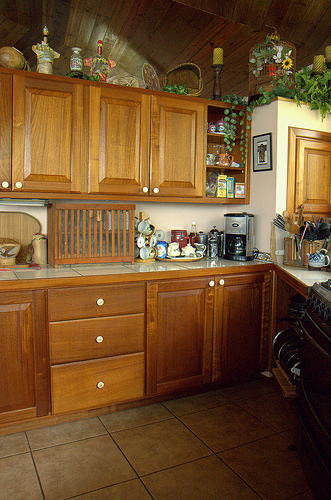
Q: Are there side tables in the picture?
A: No, there are no side tables.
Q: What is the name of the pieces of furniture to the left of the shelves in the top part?
A: The pieces of furniture are cabinets.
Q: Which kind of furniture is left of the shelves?
A: The pieces of furniture are cabinets.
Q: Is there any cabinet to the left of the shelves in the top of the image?
A: Yes, there are cabinets to the left of the shelves.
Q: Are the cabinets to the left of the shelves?
A: Yes, the cabinets are to the left of the shelves.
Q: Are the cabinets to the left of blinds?
A: No, the cabinets are to the left of the shelves.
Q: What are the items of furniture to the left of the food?
A: The pieces of furniture are cabinets.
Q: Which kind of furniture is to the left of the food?
A: The pieces of furniture are cabinets.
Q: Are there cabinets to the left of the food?
A: Yes, there are cabinets to the left of the food.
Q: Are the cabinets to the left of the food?
A: Yes, the cabinets are to the left of the food.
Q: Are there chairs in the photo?
A: No, there are no chairs.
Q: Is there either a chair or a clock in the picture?
A: No, there are no chairs or clocks.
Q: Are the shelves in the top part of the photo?
A: Yes, the shelves are in the top of the image.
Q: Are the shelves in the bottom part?
A: No, the shelves are in the top of the image.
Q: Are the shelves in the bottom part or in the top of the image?
A: The shelves are in the top of the image.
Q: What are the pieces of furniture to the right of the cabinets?
A: The pieces of furniture are shelves.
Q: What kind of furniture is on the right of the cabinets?
A: The pieces of furniture are shelves.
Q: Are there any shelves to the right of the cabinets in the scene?
A: Yes, there are shelves to the right of the cabinets.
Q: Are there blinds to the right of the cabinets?
A: No, there are shelves to the right of the cabinets.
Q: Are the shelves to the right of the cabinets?
A: Yes, the shelves are to the right of the cabinets.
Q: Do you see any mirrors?
A: No, there are no mirrors.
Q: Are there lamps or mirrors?
A: No, there are no mirrors or lamps.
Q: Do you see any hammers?
A: No, there are no hammers.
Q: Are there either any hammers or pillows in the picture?
A: No, there are no hammers or pillows.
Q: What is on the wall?
A: The decoration is on the wall.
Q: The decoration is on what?
A: The decoration is on the wall.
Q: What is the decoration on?
A: The decoration is on the wall.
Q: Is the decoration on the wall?
A: Yes, the decoration is on the wall.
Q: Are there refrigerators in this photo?
A: No, there are no refrigerators.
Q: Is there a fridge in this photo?
A: No, there are no refrigerators.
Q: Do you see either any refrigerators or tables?
A: No, there are no refrigerators or tables.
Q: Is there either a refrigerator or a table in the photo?
A: No, there are no refrigerators or tables.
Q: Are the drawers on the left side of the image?
A: Yes, the drawers are on the left of the image.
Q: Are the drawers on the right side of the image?
A: No, the drawers are on the left of the image.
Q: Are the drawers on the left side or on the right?
A: The drawers are on the left of the image.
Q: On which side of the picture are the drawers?
A: The drawers are on the left of the image.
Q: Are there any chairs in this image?
A: No, there are no chairs.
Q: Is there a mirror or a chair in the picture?
A: No, there are no chairs or mirrors.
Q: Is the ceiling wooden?
A: Yes, the ceiling is wooden.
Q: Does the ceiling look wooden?
A: Yes, the ceiling is wooden.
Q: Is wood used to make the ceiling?
A: Yes, the ceiling is made of wood.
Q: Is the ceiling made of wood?
A: Yes, the ceiling is made of wood.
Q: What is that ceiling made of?
A: The ceiling is made of wood.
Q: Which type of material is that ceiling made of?
A: The ceiling is made of wood.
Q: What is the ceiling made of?
A: The ceiling is made of wood.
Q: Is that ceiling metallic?
A: No, the ceiling is wooden.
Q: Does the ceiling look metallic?
A: No, the ceiling is wooden.